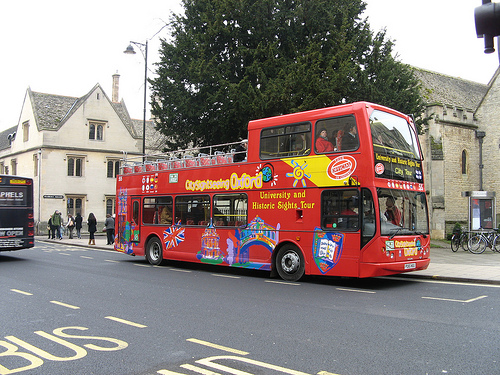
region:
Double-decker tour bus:
[112, 102, 440, 281]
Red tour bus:
[112, 100, 439, 284]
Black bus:
[0, 170, 33, 250]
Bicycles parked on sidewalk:
[448, 228, 498, 255]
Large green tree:
[146, 0, 438, 169]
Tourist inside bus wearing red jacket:
[312, 127, 337, 152]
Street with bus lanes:
[1, 234, 497, 373]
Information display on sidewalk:
[457, 185, 498, 241]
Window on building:
[65, 153, 85, 176]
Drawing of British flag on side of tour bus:
[160, 221, 187, 248]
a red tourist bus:
[113, 99, 430, 283]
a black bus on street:
[0, 175, 42, 255]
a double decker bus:
[113, 99, 427, 287]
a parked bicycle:
[466, 227, 498, 253]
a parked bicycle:
[448, 225, 470, 252]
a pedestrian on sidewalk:
[86, 210, 99, 245]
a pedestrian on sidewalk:
[70, 211, 85, 236]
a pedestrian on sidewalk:
[99, 213, 116, 243]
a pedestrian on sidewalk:
[48, 210, 64, 238]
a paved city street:
[0, 233, 495, 373]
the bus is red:
[65, 92, 435, 267]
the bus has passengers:
[154, 99, 417, 220]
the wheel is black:
[252, 237, 310, 290]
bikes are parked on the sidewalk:
[448, 203, 498, 270]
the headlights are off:
[376, 240, 438, 265]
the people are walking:
[25, 192, 133, 259]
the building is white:
[5, 85, 117, 242]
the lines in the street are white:
[20, 260, 258, 368]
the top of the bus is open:
[110, 113, 251, 166]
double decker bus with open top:
[106, 98, 443, 286]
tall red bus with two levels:
[107, 95, 446, 288]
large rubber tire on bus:
[264, 234, 312, 291]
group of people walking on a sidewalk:
[44, 203, 116, 252]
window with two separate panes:
[63, 150, 89, 182]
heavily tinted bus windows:
[251, 106, 365, 158]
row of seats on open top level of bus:
[112, 148, 245, 175]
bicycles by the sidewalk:
[447, 214, 498, 259]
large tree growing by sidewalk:
[135, 0, 434, 163]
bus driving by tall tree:
[97, 89, 443, 305]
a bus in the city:
[32, 46, 479, 309]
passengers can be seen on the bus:
[115, 113, 440, 287]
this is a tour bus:
[245, 186, 320, 217]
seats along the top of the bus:
[111, 148, 241, 180]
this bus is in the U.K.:
[155, 218, 188, 253]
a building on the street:
[5, 79, 149, 239]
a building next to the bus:
[397, 61, 499, 275]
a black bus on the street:
[0, 162, 45, 267]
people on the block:
[40, 202, 117, 247]